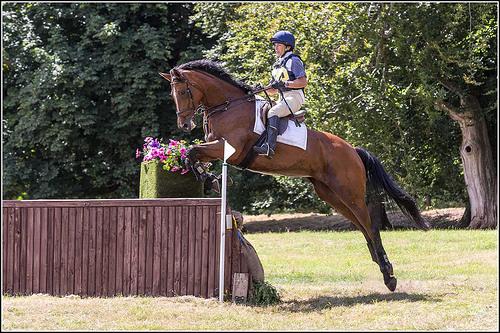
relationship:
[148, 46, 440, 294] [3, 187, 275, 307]
horse jumping over an obstacle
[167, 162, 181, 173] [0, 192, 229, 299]
flower on a fence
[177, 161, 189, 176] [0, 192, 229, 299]
flower on a fence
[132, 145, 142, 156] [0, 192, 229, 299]
flower on a fence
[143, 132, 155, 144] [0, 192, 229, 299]
flower on a fence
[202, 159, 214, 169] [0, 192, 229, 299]
flower on a fence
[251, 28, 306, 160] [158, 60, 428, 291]
horseback rider on a horse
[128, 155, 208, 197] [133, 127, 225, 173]
box for flowers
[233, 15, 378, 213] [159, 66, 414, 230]
woman riding on horse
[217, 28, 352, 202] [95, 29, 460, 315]
someone riding a horse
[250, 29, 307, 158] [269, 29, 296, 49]
person wearing a helmet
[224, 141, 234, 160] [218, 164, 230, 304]
white flag on pole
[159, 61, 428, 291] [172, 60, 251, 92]
brown horse has black mane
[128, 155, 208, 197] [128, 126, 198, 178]
box has flowers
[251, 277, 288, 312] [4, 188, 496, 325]
weeds on ground